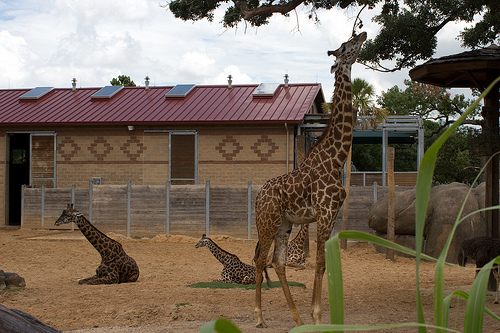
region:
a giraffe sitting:
[50, 200, 142, 287]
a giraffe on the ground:
[192, 232, 257, 290]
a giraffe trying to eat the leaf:
[250, 21, 378, 329]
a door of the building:
[3, 130, 30, 232]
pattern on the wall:
[55, 134, 151, 163]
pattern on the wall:
[201, 133, 288, 168]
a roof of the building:
[6, 82, 321, 122]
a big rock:
[370, 183, 484, 265]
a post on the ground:
[381, 145, 400, 261]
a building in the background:
[1, 78, 328, 234]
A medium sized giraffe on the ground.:
[53, 192, 150, 291]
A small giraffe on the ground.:
[181, 230, 256, 288]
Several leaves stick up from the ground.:
[324, 168, 488, 331]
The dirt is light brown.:
[46, 280, 80, 320]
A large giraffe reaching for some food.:
[207, 30, 377, 312]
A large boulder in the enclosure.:
[372, 183, 490, 260]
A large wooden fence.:
[17, 180, 250, 238]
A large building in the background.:
[6, 81, 305, 226]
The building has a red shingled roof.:
[48, 91, 86, 116]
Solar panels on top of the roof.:
[164, 76, 196, 101]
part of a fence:
[223, 190, 229, 213]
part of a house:
[228, 136, 233, 154]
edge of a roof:
[146, 244, 153, 271]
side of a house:
[211, 148, 221, 163]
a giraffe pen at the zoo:
[12, 91, 459, 331]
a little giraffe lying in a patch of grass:
[182, 231, 276, 295]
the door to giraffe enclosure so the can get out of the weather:
[6, 125, 61, 241]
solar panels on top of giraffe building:
[22, 82, 295, 122]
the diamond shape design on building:
[215, 137, 297, 164]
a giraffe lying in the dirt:
[36, 195, 163, 302]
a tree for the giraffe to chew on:
[356, 10, 446, 73]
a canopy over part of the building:
[311, 97, 447, 198]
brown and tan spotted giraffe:
[55, 203, 135, 283]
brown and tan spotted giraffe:
[195, 226, 255, 301]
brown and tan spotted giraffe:
[274, 15, 371, 309]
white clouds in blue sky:
[31, 18, 69, 43]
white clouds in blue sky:
[78, 23, 115, 47]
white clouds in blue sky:
[21, 6, 66, 50]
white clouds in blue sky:
[268, 36, 298, 58]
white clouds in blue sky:
[202, 48, 239, 68]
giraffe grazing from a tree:
[210, 27, 375, 322]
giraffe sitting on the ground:
[48, 199, 158, 294]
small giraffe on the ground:
[180, 219, 267, 286]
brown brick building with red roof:
[7, 65, 314, 195]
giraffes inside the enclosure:
[53, 32, 368, 331]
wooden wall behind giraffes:
[16, 181, 402, 245]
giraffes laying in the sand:
[53, 196, 309, 283]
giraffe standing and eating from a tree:
[252, 32, 369, 331]